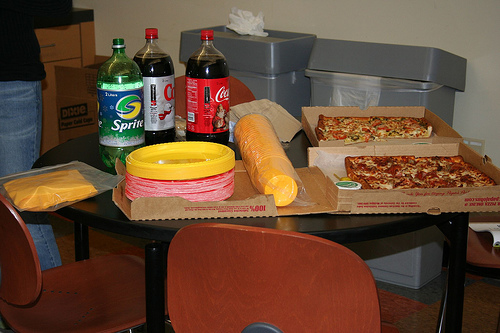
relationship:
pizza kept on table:
[335, 148, 482, 195] [28, 96, 479, 258]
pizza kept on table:
[315, 106, 444, 146] [28, 96, 479, 258]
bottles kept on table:
[87, 16, 239, 173] [22, 88, 481, 329]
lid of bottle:
[138, 24, 214, 40] [184, 42, 229, 146]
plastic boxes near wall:
[173, 18, 472, 290] [104, 8, 475, 168]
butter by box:
[331, 170, 372, 210] [297, 106, 462, 147]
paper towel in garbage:
[474, 216, 483, 240] [214, 36, 319, 113]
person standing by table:
[4, 47, 58, 296] [53, 130, 237, 264]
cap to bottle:
[200, 27, 215, 39] [184, 28, 231, 143]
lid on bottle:
[144, 25, 160, 41] [136, 23, 176, 143]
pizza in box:
[315, 113, 432, 140] [290, 99, 482, 142]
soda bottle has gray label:
[139, 29, 176, 138] [144, 77, 174, 130]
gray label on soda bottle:
[144, 77, 174, 130] [139, 29, 176, 138]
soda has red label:
[185, 27, 229, 143] [183, 72, 233, 135]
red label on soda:
[183, 72, 233, 135] [185, 27, 229, 143]